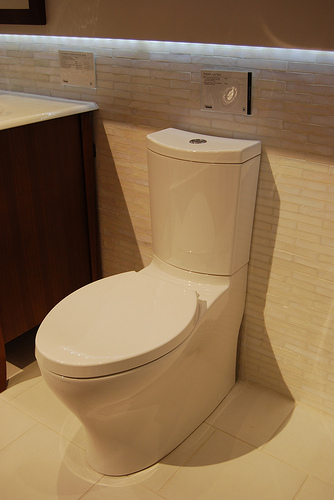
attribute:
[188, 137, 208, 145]
button — toilet flusher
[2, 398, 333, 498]
floor — white 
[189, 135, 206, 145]
button — silver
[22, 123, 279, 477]
toilet — white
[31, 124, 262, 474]
toilet — white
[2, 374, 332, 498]
floor — white, tile